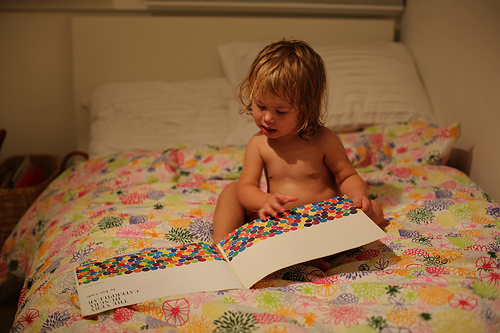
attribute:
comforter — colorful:
[57, 151, 207, 236]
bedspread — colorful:
[93, 167, 398, 321]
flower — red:
[92, 211, 124, 235]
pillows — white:
[218, 36, 437, 133]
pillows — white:
[87, 80, 249, 160]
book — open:
[74, 193, 385, 318]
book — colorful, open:
[98, 193, 395, 295]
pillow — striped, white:
[87, 80, 257, 167]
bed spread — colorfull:
[3, 116, 498, 329]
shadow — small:
[445, 143, 477, 178]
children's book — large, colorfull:
[74, 192, 386, 318]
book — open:
[24, 206, 443, 323]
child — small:
[238, 37, 372, 199]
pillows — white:
[79, 36, 459, 151]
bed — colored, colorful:
[21, 9, 498, 331]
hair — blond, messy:
[214, 27, 359, 167]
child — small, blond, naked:
[220, 38, 408, 261]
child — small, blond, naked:
[222, 55, 372, 188]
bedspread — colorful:
[376, 123, 472, 331]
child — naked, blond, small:
[205, 31, 389, 257]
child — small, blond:
[209, 35, 393, 246]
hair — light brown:
[243, 37, 327, 136]